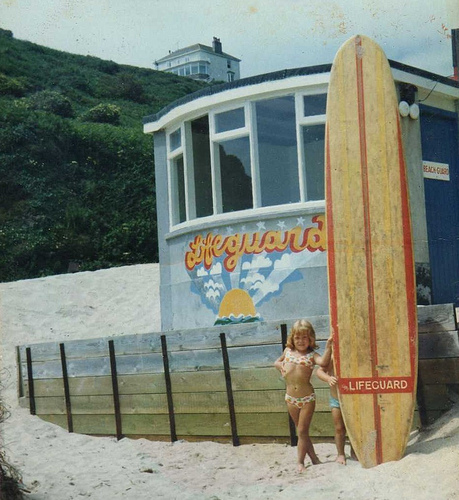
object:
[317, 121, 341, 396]
stripe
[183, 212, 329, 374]
sign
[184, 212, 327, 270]
lifeguard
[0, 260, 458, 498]
beach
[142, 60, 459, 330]
house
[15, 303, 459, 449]
fence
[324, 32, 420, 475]
board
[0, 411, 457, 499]
sand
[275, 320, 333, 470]
girl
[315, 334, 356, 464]
boy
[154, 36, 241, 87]
house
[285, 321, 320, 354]
hair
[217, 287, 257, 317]
sun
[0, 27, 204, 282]
hillside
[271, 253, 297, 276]
clouds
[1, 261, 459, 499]
ground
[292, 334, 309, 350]
face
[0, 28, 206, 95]
hill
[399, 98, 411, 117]
light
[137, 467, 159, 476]
grass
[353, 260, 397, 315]
part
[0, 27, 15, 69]
part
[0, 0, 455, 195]
background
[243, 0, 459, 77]
sky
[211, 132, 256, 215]
window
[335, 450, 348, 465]
foot